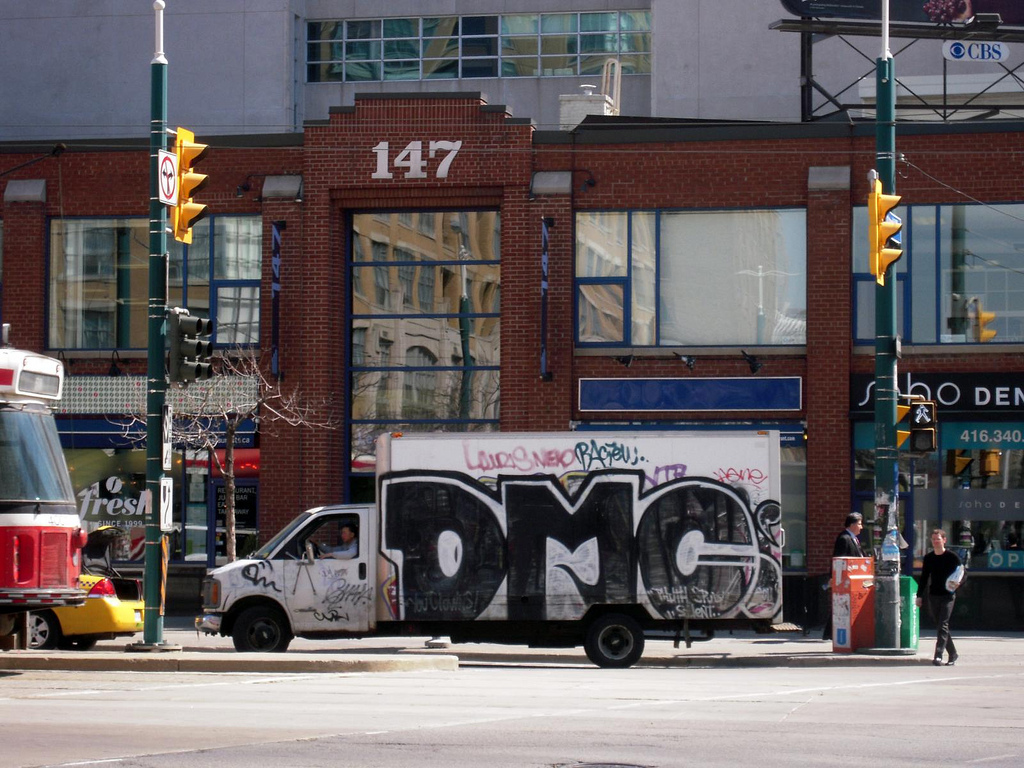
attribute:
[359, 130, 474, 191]
numbers — large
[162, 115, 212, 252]
traffic light — yellow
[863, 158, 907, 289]
traffic light — painted yellow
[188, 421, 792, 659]
truck — white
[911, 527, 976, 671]
man — walking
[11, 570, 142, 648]
taxi — yellow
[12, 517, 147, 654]
taxi truck — open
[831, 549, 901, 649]
box — red, newspaper